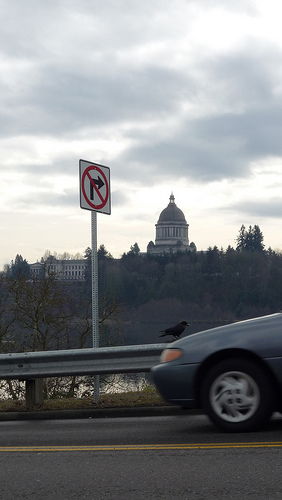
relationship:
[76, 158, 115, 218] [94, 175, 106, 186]
sign has arrow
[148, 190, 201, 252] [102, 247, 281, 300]
building behind trees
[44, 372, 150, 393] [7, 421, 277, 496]
water beside road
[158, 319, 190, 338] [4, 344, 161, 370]
bird on railing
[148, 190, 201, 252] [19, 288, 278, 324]
building on hill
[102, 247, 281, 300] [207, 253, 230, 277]
trees with leaves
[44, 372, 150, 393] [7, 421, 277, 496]
water next to road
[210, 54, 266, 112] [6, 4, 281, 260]
cloud in sky